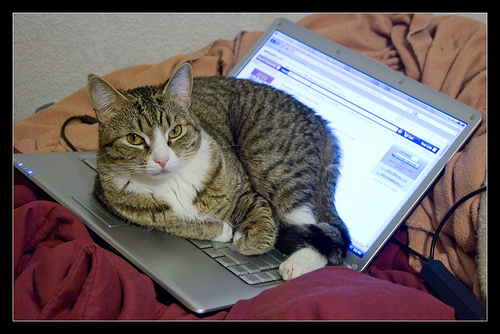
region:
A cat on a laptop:
[88, 56, 350, 285]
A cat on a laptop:
[82, 57, 348, 283]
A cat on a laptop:
[82, 55, 352, 285]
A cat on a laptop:
[80, 56, 356, 286]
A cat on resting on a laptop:
[84, 57, 356, 281]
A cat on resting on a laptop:
[85, 57, 350, 279]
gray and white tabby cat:
[88, 65, 349, 277]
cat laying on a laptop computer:
[15, 22, 482, 314]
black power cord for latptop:
[391, 195, 483, 314]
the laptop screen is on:
[210, 15, 480, 273]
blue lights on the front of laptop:
[15, 161, 32, 178]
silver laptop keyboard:
[23, 151, 295, 313]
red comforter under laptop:
[12, 153, 454, 333]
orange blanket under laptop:
[15, 14, 487, 281]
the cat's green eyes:
[127, 126, 179, 143]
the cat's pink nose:
[155, 154, 167, 166]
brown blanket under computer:
[15, 15, 485, 287]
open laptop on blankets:
[14, 19, 479, 315]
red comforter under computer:
[12, 183, 438, 319]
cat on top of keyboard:
[87, 58, 347, 281]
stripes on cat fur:
[209, 79, 324, 201]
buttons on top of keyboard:
[212, 249, 284, 282]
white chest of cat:
[119, 176, 211, 215]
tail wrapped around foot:
[280, 179, 349, 264]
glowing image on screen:
[222, 28, 469, 254]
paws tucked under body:
[204, 208, 277, 255]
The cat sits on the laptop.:
[18, 23, 475, 304]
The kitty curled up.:
[85, 60, 347, 279]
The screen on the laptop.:
[247, 45, 447, 198]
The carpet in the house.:
[24, 19, 247, 56]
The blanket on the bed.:
[26, 206, 121, 318]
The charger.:
[397, 228, 484, 318]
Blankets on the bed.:
[400, 15, 484, 77]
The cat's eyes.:
[122, 122, 192, 145]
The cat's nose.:
[147, 153, 172, 166]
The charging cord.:
[439, 186, 480, 226]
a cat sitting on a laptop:
[72, 45, 353, 288]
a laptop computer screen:
[219, 12, 476, 252]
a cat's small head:
[91, 80, 204, 176]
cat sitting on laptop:
[75, 59, 359, 284]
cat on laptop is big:
[76, 56, 357, 289]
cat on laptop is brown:
[76, 61, 363, 289]